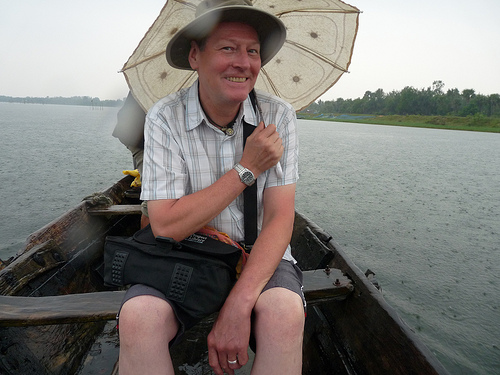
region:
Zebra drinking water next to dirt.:
[129, 111, 210, 211]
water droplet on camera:
[94, 89, 146, 149]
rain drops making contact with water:
[399, 273, 414, 303]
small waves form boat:
[434, 317, 470, 367]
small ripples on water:
[421, 188, 486, 322]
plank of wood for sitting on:
[5, 291, 115, 316]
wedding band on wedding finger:
[226, 353, 238, 363]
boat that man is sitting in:
[306, 212, 446, 370]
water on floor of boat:
[78, 340, 110, 365]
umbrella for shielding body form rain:
[118, 0, 360, 115]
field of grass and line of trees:
[411, 88, 491, 128]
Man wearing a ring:
[225, 352, 240, 364]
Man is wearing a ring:
[222, 355, 241, 365]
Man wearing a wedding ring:
[222, 355, 240, 367]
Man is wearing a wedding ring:
[222, 350, 241, 365]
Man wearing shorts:
[99, 243, 311, 328]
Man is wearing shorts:
[117, 235, 314, 356]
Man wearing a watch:
[232, 160, 262, 187]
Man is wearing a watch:
[230, 157, 266, 189]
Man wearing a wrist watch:
[230, 159, 258, 191]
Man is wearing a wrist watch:
[231, 157, 258, 187]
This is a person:
[112, 0, 346, 374]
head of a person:
[175, 11, 287, 136]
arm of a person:
[137, 134, 271, 242]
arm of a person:
[203, 173, 313, 315]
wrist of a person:
[195, 279, 285, 318]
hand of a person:
[168, 314, 297, 369]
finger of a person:
[193, 328, 267, 372]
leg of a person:
[106, 305, 183, 370]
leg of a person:
[236, 310, 324, 373]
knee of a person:
[96, 281, 174, 338]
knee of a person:
[240, 277, 337, 332]